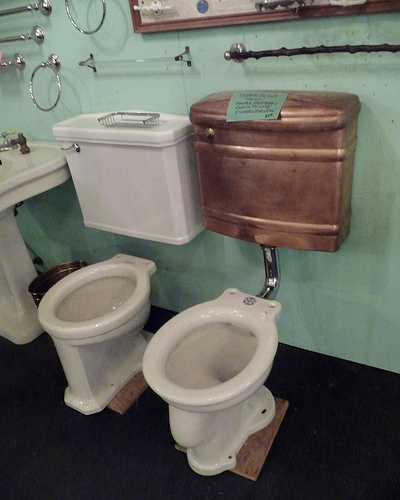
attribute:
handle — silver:
[61, 142, 80, 152]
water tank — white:
[51, 108, 206, 244]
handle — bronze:
[187, 126, 216, 140]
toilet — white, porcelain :
[144, 286, 280, 476]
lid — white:
[142, 290, 278, 401]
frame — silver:
[249, 245, 284, 304]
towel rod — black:
[226, 42, 399, 64]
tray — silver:
[96, 110, 160, 131]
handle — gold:
[190, 127, 215, 140]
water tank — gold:
[189, 91, 350, 251]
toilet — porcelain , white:
[36, 251, 156, 415]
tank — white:
[52, 110, 205, 247]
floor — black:
[9, 301, 393, 496]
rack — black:
[216, 35, 398, 67]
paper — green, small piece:
[227, 90, 288, 120]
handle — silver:
[51, 142, 85, 160]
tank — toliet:
[37, 260, 144, 417]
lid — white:
[51, 112, 189, 147]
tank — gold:
[188, 88, 361, 253]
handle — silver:
[223, 41, 245, 63]